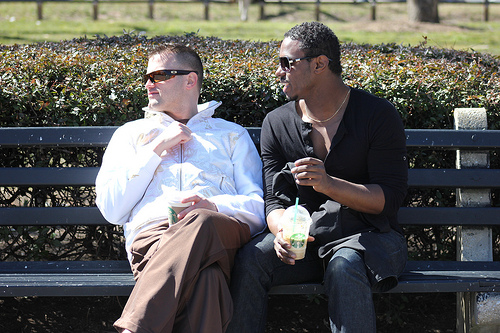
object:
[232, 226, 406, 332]
pants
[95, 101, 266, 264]
jacket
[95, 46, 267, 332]
man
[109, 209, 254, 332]
pants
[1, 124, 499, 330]
bench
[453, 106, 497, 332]
pillar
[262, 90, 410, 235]
shirt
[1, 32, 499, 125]
plants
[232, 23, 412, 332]
man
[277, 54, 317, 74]
sunglasses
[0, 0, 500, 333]
bushes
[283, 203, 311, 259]
cup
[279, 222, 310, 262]
hand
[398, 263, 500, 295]
wood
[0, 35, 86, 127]
hedge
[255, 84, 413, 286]
jacket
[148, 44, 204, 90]
hair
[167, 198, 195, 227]
drink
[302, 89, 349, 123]
necklace